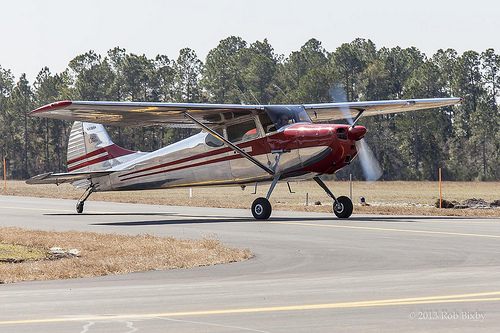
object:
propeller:
[325, 80, 384, 185]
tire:
[251, 197, 272, 222]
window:
[226, 120, 258, 143]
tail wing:
[25, 170, 115, 186]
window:
[258, 105, 313, 134]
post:
[439, 168, 443, 210]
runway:
[0, 195, 500, 333]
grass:
[119, 245, 155, 271]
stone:
[45, 244, 83, 261]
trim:
[253, 202, 265, 216]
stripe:
[66, 144, 137, 173]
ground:
[0, 180, 500, 333]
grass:
[0, 242, 50, 262]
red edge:
[27, 100, 73, 115]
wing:
[26, 100, 263, 132]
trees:
[0, 72, 40, 181]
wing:
[301, 97, 464, 123]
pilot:
[265, 112, 291, 133]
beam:
[182, 111, 276, 177]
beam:
[351, 110, 365, 127]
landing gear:
[312, 175, 354, 219]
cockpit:
[224, 104, 313, 183]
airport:
[25, 80, 463, 220]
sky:
[0, 0, 500, 90]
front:
[333, 196, 354, 220]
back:
[74, 200, 84, 213]